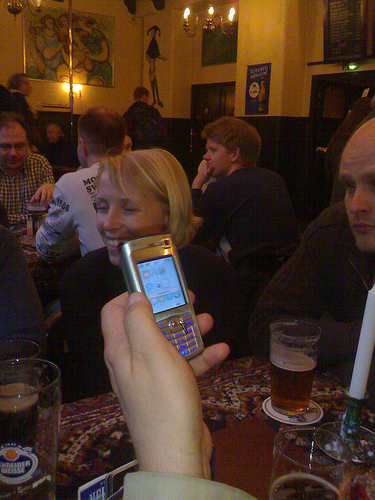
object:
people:
[255, 107, 374, 343]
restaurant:
[4, 0, 369, 500]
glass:
[263, 315, 326, 417]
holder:
[316, 388, 374, 463]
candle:
[350, 279, 373, 399]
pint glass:
[0, 360, 62, 496]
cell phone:
[117, 230, 205, 361]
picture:
[23, 10, 114, 90]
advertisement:
[245, 61, 272, 116]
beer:
[258, 82, 267, 114]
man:
[192, 117, 297, 249]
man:
[1, 120, 57, 233]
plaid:
[4, 175, 28, 201]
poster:
[144, 57, 163, 110]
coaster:
[259, 395, 324, 432]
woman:
[70, 150, 234, 362]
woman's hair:
[115, 149, 198, 247]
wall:
[34, 6, 316, 115]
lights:
[179, 6, 191, 21]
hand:
[92, 296, 230, 465]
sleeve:
[113, 467, 246, 497]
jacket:
[256, 205, 372, 365]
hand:
[196, 158, 214, 182]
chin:
[206, 166, 219, 178]